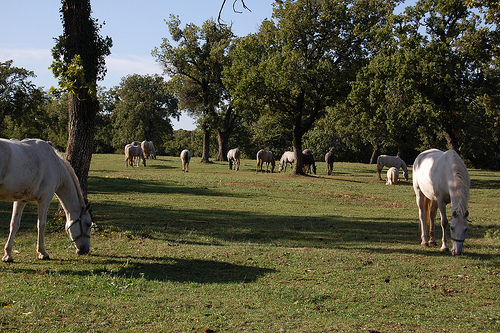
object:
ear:
[451, 208, 461, 219]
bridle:
[67, 197, 92, 246]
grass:
[1, 155, 496, 332]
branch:
[214, 2, 226, 37]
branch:
[241, 0, 257, 15]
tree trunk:
[57, 36, 105, 173]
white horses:
[4, 134, 97, 259]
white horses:
[174, 144, 199, 176]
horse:
[123, 142, 144, 168]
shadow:
[80, 244, 271, 289]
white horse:
[402, 148, 477, 253]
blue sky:
[1, 0, 50, 26]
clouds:
[3, 42, 52, 59]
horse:
[276, 149, 294, 171]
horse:
[177, 150, 187, 171]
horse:
[278, 150, 298, 173]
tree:
[223, 0, 394, 175]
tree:
[346, 52, 496, 180]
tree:
[156, 17, 247, 169]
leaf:
[308, 65, 323, 80]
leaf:
[264, 60, 272, 72]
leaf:
[357, 31, 366, 37]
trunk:
[60, 2, 108, 159]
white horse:
[410, 146, 470, 256]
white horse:
[0, 135, 93, 265]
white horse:
[256, 146, 276, 170]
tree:
[62, 47, 97, 132]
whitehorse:
[376, 152, 410, 184]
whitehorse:
[278, 145, 291, 169]